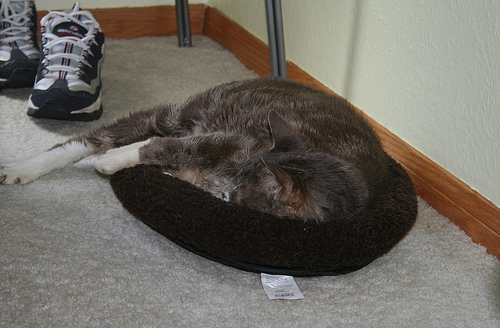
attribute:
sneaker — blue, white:
[17, 5, 114, 125]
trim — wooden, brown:
[0, 2, 499, 261]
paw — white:
[94, 140, 146, 180]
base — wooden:
[95, 4, 294, 69]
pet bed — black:
[107, 155, 419, 280]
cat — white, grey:
[34, 72, 400, 224]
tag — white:
[257, 273, 303, 302]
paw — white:
[0, 140, 94, 184]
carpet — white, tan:
[7, 34, 498, 318]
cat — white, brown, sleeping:
[14, 72, 408, 232]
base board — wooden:
[29, 4, 496, 278]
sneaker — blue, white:
[1, 0, 41, 99]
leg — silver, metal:
[261, 3, 290, 73]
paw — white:
[8, 141, 89, 187]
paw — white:
[74, 138, 147, 176]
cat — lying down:
[1, 77, 392, 217]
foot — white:
[95, 135, 144, 175]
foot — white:
[2, 140, 96, 188]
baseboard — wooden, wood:
[34, 4, 484, 261]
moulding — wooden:
[33, 2, 483, 252]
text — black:
[263, 273, 294, 297]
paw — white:
[2, 138, 96, 188]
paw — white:
[91, 134, 150, 174]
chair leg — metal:
[172, 0, 195, 49]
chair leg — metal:
[262, 0, 287, 77]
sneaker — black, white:
[2, 0, 46, 89]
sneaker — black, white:
[25, 3, 107, 123]